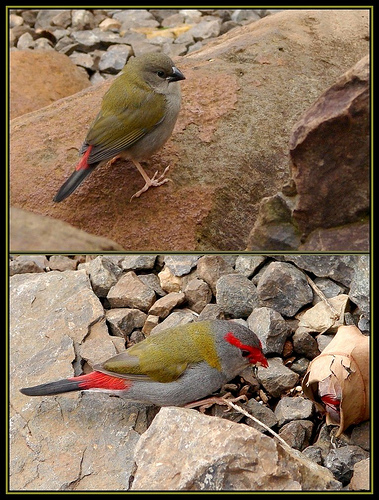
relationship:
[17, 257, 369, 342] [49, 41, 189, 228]
rocks below bird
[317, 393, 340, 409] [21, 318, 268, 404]
item near bird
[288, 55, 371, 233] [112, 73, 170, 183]
rock below bird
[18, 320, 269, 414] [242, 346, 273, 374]
bird with beak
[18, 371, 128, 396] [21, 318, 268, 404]
tail on bird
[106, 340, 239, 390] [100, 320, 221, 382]
bird with wing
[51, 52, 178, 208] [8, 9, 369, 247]
bird sitting on rock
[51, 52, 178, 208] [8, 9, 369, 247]
bird on rock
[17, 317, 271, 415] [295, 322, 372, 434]
trash in front of bird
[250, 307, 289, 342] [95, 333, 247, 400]
pebble in front of bird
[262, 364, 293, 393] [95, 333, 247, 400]
pebble in front of bird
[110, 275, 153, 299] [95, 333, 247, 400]
pebble behind bird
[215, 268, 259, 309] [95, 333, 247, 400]
pebble behind bird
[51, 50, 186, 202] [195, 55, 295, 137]
bird standing on rock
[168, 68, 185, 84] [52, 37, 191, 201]
beak on bird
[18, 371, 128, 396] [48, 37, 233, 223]
tail of bird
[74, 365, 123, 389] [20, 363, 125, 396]
feathers on tail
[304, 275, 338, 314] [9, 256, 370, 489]
twig in rocks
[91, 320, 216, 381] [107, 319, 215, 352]
feathers on back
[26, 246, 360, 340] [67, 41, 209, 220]
rock under bird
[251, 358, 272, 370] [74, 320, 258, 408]
beak on bird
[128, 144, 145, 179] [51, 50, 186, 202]
leg on bird